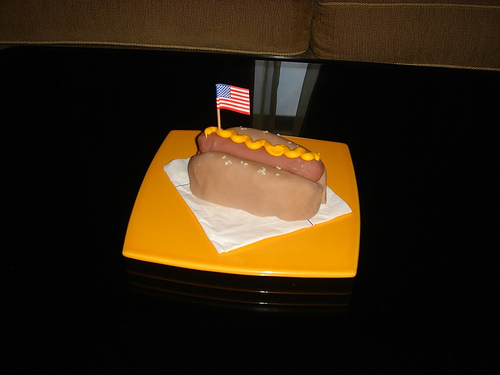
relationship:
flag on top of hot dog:
[215, 83, 250, 117] [197, 127, 325, 182]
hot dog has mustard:
[197, 127, 325, 182] [204, 126, 321, 162]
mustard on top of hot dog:
[204, 126, 321, 162] [197, 127, 325, 182]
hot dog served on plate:
[197, 127, 325, 182] [121, 128, 361, 279]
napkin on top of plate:
[162, 156, 353, 255] [121, 128, 361, 279]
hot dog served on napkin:
[197, 127, 325, 182] [162, 156, 353, 255]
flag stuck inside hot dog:
[215, 83, 250, 117] [197, 127, 325, 182]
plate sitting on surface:
[121, 128, 361, 279] [1, 43, 499, 374]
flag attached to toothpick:
[215, 83, 250, 117] [216, 110, 221, 131]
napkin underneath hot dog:
[162, 156, 353, 255] [197, 127, 325, 182]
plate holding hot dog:
[121, 128, 361, 279] [197, 127, 325, 182]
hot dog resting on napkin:
[197, 127, 325, 182] [162, 156, 353, 255]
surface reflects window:
[1, 43, 499, 374] [249, 58, 322, 137]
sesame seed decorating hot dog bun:
[276, 133, 280, 137] [188, 126, 329, 221]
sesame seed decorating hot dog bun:
[287, 141, 292, 146] [188, 126, 329, 221]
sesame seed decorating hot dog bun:
[221, 156, 226, 159] [188, 126, 329, 221]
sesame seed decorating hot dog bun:
[243, 162, 247, 165] [188, 126, 329, 221]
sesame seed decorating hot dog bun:
[275, 172, 280, 178] [188, 126, 329, 221]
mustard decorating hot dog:
[204, 126, 321, 162] [197, 127, 325, 182]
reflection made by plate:
[123, 268, 353, 309] [121, 128, 361, 279]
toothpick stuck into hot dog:
[216, 110, 221, 131] [197, 127, 325, 182]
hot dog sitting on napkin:
[197, 127, 325, 182] [162, 156, 353, 255]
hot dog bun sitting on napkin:
[188, 126, 329, 221] [162, 156, 353, 255]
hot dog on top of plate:
[197, 127, 325, 182] [121, 128, 361, 279]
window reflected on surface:
[249, 58, 322, 137] [1, 43, 499, 374]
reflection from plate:
[123, 268, 353, 309] [121, 128, 361, 279]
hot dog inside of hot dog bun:
[197, 127, 325, 182] [188, 126, 329, 221]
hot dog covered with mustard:
[197, 127, 325, 182] [204, 126, 321, 162]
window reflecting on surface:
[249, 58, 322, 137] [1, 43, 499, 374]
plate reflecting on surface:
[121, 128, 361, 279] [1, 43, 499, 374]